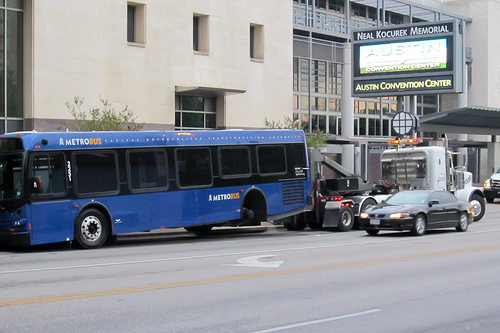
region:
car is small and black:
[357, 179, 488, 249]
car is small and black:
[355, 162, 471, 252]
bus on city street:
[18, 49, 440, 259]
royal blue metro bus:
[20, 107, 307, 228]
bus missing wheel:
[212, 173, 299, 243]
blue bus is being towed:
[210, 107, 460, 222]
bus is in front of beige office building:
[76, 14, 291, 119]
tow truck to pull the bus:
[295, 128, 484, 225]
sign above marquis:
[334, 14, 460, 104]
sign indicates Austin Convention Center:
[339, 73, 470, 100]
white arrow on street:
[203, 234, 332, 300]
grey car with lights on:
[356, 187, 482, 251]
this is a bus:
[0, 127, 305, 227]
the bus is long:
[15, 133, 310, 230]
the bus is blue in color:
[16, 131, 306, 238]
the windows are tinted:
[213, 148, 276, 172]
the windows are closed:
[144, 150, 211, 186]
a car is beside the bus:
[365, 187, 470, 232]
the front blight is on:
[389, 210, 404, 219]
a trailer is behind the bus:
[337, 142, 447, 187]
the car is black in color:
[370, 194, 474, 239]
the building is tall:
[212, 19, 239, 79]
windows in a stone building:
[124, 2, 271, 63]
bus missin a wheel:
[240, 197, 271, 239]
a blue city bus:
[9, 128, 316, 245]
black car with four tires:
[334, 189, 469, 242]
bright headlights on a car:
[353, 207, 403, 222]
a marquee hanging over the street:
[358, 41, 451, 80]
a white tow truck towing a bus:
[14, 125, 468, 206]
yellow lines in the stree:
[89, 282, 237, 293]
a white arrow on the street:
[219, 245, 292, 279]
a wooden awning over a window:
[188, 85, 258, 99]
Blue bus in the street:
[13, 120, 325, 280]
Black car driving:
[364, 191, 489, 252]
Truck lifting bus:
[298, 140, 378, 241]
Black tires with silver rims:
[52, 196, 136, 273]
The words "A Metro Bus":
[49, 135, 122, 153]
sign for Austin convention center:
[329, 32, 492, 122]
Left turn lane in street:
[183, 253, 385, 295]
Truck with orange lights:
[372, 131, 485, 195]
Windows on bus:
[75, 141, 287, 201]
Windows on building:
[98, 17, 289, 78]